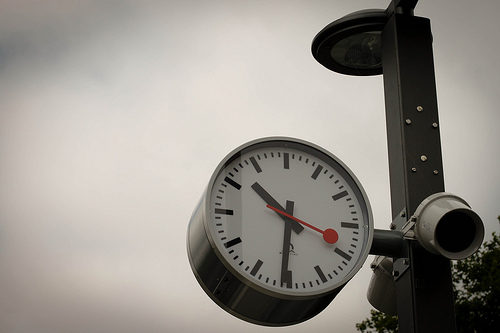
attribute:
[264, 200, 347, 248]
hand — red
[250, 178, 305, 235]
hand — black, short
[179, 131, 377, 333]
clock — outdoor, black, white, round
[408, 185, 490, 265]
camera — grey, closed circut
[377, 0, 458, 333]
pole — black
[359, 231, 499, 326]
tree — dark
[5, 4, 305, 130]
sky — white, grey, overcast, stormy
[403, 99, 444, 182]
bolts — silver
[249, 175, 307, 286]
hands — black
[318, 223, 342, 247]
circle — red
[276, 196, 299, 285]
hand — long